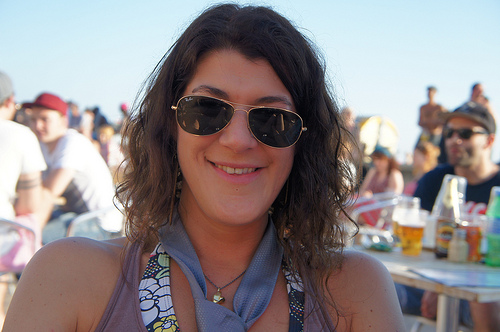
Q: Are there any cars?
A: No, there are no cars.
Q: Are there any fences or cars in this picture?
A: No, there are no cars or fences.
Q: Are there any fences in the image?
A: No, there are no fences.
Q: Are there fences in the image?
A: No, there are no fences.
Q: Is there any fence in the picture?
A: No, there are no fences.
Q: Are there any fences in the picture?
A: No, there are no fences.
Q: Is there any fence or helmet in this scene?
A: No, there are no fences or helmets.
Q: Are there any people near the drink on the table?
A: Yes, there is a person near the drink.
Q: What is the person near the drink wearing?
A: The person is wearing a cap.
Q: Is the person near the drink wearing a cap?
A: Yes, the person is wearing a cap.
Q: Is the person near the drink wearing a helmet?
A: No, the person is wearing a cap.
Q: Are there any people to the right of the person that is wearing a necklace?
A: Yes, there is a person to the right of the woman.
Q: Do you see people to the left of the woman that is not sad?
A: No, the person is to the right of the woman.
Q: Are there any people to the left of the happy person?
A: No, the person is to the right of the woman.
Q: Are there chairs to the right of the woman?
A: No, there is a person to the right of the woman.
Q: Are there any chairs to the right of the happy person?
A: No, there is a person to the right of the woman.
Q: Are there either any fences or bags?
A: No, there are no bags or fences.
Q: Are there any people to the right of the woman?
A: Yes, there is a person to the right of the woman.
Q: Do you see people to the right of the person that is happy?
A: Yes, there is a person to the right of the woman.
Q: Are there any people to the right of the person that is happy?
A: Yes, there is a person to the right of the woman.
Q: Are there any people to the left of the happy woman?
A: No, the person is to the right of the woman.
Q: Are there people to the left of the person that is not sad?
A: No, the person is to the right of the woman.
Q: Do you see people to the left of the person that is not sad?
A: No, the person is to the right of the woman.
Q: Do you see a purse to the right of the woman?
A: No, there is a person to the right of the woman.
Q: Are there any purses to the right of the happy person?
A: No, there is a person to the right of the woman.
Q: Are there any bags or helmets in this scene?
A: No, there are no bags or helmets.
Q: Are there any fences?
A: No, there are no fences.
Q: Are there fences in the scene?
A: No, there are no fences.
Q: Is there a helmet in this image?
A: No, there are no helmets.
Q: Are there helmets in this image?
A: No, there are no helmets.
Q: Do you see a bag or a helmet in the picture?
A: No, there are no helmets or bags.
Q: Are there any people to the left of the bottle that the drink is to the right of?
A: Yes, there is a person to the left of the bottle.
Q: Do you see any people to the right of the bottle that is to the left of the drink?
A: No, the person is to the left of the bottle.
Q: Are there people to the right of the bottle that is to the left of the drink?
A: No, the person is to the left of the bottle.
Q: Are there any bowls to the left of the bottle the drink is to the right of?
A: No, there is a person to the left of the bottle.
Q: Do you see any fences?
A: No, there are no fences.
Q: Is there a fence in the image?
A: No, there are no fences.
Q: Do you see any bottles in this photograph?
A: Yes, there is a bottle.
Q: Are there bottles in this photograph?
A: Yes, there is a bottle.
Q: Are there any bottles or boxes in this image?
A: Yes, there is a bottle.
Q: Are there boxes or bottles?
A: Yes, there is a bottle.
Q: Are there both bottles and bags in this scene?
A: No, there is a bottle but no bags.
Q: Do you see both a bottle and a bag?
A: No, there is a bottle but no bags.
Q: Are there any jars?
A: No, there are no jars.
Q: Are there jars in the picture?
A: No, there are no jars.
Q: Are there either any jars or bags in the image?
A: No, there are no jars or bags.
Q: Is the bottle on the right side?
A: Yes, the bottle is on the right of the image.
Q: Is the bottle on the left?
A: No, the bottle is on the right of the image.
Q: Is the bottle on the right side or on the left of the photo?
A: The bottle is on the right of the image.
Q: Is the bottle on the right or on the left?
A: The bottle is on the right of the image.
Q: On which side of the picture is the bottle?
A: The bottle is on the right of the image.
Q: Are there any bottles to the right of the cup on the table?
A: Yes, there is a bottle to the right of the cup.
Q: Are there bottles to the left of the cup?
A: No, the bottle is to the right of the cup.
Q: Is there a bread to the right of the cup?
A: No, there is a bottle to the right of the cup.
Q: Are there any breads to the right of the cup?
A: No, there is a bottle to the right of the cup.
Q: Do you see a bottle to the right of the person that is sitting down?
A: Yes, there is a bottle to the right of the person.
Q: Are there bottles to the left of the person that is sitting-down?
A: No, the bottle is to the right of the person.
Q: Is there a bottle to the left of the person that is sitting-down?
A: No, the bottle is to the right of the person.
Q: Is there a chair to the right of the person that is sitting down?
A: No, there is a bottle to the right of the person.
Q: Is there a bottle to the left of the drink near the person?
A: Yes, there is a bottle to the left of the drink.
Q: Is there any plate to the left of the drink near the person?
A: No, there is a bottle to the left of the drink.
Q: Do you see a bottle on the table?
A: Yes, there is a bottle on the table.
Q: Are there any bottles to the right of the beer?
A: Yes, there is a bottle to the right of the beer.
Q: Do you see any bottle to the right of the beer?
A: Yes, there is a bottle to the right of the beer.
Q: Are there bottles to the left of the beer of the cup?
A: No, the bottle is to the right of the beer.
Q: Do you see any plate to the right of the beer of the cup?
A: No, there is a bottle to the right of the beer.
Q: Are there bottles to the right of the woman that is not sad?
A: Yes, there is a bottle to the right of the woman.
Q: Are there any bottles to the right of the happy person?
A: Yes, there is a bottle to the right of the woman.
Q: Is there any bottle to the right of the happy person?
A: Yes, there is a bottle to the right of the woman.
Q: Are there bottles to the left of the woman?
A: No, the bottle is to the right of the woman.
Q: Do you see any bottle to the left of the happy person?
A: No, the bottle is to the right of the woman.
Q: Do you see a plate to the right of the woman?
A: No, there is a bottle to the right of the woman.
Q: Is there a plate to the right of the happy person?
A: No, there is a bottle to the right of the woman.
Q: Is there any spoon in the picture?
A: No, there are no spoons.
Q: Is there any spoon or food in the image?
A: No, there are no spoons or food.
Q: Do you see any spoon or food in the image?
A: No, there are no spoons or food.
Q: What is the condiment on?
A: The condiment is on the table.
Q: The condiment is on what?
A: The condiment is on the table.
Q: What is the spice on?
A: The condiment is on the table.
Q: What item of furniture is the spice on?
A: The spice is on the table.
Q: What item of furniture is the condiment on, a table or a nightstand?
A: The condiment is on a table.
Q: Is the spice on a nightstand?
A: No, the spice is on the table.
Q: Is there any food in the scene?
A: No, there is no food.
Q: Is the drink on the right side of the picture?
A: Yes, the drink is on the right of the image.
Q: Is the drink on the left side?
A: No, the drink is on the right of the image.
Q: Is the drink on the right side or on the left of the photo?
A: The drink is on the right of the image.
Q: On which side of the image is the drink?
A: The drink is on the right of the image.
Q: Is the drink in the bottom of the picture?
A: Yes, the drink is in the bottom of the image.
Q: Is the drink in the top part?
A: No, the drink is in the bottom of the image.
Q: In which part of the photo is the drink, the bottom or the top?
A: The drink is in the bottom of the image.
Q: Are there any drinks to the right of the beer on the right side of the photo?
A: Yes, there is a drink to the right of the beer.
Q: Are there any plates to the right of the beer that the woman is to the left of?
A: No, there is a drink to the right of the beer.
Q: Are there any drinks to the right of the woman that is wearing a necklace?
A: Yes, there is a drink to the right of the woman.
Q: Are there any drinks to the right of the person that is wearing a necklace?
A: Yes, there is a drink to the right of the woman.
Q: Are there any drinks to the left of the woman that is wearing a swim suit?
A: No, the drink is to the right of the woman.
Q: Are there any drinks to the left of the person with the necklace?
A: No, the drink is to the right of the woman.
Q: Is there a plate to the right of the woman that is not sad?
A: No, there is a drink to the right of the woman.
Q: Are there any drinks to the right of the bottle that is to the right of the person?
A: Yes, there is a drink to the right of the bottle.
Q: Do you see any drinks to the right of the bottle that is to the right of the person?
A: Yes, there is a drink to the right of the bottle.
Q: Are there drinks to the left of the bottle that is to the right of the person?
A: No, the drink is to the right of the bottle.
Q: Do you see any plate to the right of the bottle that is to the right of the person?
A: No, there is a drink to the right of the bottle.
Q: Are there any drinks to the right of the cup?
A: Yes, there is a drink to the right of the cup.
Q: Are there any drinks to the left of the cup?
A: No, the drink is to the right of the cup.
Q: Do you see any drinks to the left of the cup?
A: No, the drink is to the right of the cup.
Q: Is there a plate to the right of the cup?
A: No, there is a drink to the right of the cup.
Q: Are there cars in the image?
A: No, there are no cars.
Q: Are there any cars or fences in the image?
A: No, there are no cars or fences.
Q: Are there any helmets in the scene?
A: No, there are no helmets.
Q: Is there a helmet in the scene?
A: No, there are no helmets.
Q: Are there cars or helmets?
A: No, there are no helmets or cars.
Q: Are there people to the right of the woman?
A: Yes, there is a person to the right of the woman.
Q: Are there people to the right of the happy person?
A: Yes, there is a person to the right of the woman.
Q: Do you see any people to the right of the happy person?
A: Yes, there is a person to the right of the woman.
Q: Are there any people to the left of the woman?
A: No, the person is to the right of the woman.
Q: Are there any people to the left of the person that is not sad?
A: No, the person is to the right of the woman.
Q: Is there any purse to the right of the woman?
A: No, there is a person to the right of the woman.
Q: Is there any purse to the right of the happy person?
A: No, there is a person to the right of the woman.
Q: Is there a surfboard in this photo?
A: No, there are no surfboards.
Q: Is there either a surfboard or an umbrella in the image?
A: No, there are no surfboards or umbrellas.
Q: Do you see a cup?
A: Yes, there is a cup.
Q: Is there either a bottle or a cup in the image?
A: Yes, there is a cup.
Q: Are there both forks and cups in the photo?
A: No, there is a cup but no forks.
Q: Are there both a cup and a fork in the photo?
A: No, there is a cup but no forks.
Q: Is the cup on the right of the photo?
A: Yes, the cup is on the right of the image.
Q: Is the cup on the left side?
A: No, the cup is on the right of the image.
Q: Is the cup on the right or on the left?
A: The cup is on the right of the image.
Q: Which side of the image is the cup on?
A: The cup is on the right of the image.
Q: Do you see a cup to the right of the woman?
A: Yes, there is a cup to the right of the woman.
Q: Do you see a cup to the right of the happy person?
A: Yes, there is a cup to the right of the woman.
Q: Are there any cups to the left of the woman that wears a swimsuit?
A: No, the cup is to the right of the woman.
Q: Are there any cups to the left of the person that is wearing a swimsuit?
A: No, the cup is to the right of the woman.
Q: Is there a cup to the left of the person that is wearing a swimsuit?
A: No, the cup is to the right of the woman.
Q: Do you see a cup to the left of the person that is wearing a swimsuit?
A: No, the cup is to the right of the woman.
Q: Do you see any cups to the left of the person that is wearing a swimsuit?
A: No, the cup is to the right of the woman.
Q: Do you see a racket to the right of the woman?
A: No, there is a cup to the right of the woman.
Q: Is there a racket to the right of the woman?
A: No, there is a cup to the right of the woman.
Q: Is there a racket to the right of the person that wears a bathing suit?
A: No, there is a cup to the right of the woman.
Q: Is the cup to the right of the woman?
A: Yes, the cup is to the right of the woman.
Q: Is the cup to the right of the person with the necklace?
A: Yes, the cup is to the right of the woman.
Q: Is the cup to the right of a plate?
A: No, the cup is to the right of the woman.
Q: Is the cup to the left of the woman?
A: No, the cup is to the right of the woman.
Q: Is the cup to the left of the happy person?
A: No, the cup is to the right of the woman.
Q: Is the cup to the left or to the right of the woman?
A: The cup is to the right of the woman.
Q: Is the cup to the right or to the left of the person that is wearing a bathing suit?
A: The cup is to the right of the woman.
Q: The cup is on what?
A: The cup is on the table.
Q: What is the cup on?
A: The cup is on the table.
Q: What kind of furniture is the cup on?
A: The cup is on the table.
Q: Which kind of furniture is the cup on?
A: The cup is on the table.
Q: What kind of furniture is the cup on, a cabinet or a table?
A: The cup is on a table.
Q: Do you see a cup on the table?
A: Yes, there is a cup on the table.